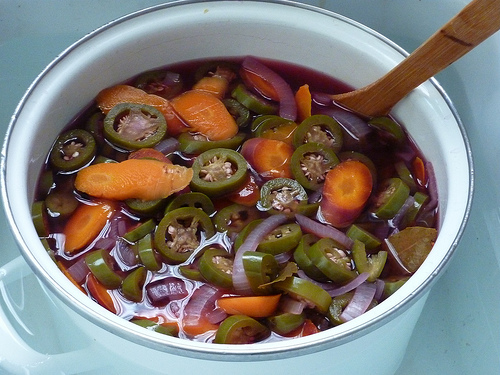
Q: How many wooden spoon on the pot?
A: One.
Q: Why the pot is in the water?
A: To cool it down.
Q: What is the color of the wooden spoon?
A: Brown.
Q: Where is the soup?
A: In a pot.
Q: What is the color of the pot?
A: White.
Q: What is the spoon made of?
A: Wood.